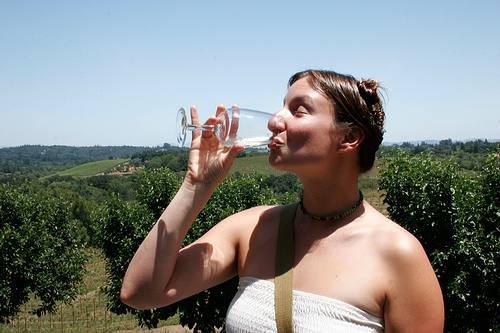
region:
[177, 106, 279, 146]
wine glass with a clear liquid in it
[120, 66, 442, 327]
a woman is drinking a clear liquid out of a wine glass on a very sunny day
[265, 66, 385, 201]
woman has brown hair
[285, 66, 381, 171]
hair is pinned up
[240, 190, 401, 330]
woman has a brown strap across her shoulder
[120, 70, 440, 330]
woman is using her right hand to drink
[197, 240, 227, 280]
you can see the reflection from the wine glass on the woman arm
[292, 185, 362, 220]
woman is wearing a necklace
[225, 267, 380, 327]
woman is wearing a tube top shirt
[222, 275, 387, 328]
tube top shirt is white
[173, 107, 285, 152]
an empty wine glass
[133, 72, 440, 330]
a woman drinking wine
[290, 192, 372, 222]
a beaded necklace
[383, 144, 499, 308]
a tree with dark green leaves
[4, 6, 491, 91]
a sunny blue sky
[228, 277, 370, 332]
a strapless white top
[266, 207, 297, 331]
a purse strap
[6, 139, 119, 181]
a mountain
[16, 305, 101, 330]
a metal fence by the trees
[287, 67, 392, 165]
dark hair pulled back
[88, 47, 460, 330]
woman holding wine glass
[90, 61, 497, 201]
woman with short hair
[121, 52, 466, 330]
woman wearing strapless top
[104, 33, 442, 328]
woman with brown hair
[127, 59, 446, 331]
woman with big nose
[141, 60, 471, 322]
woman wearing white top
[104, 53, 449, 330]
woman standing in vineyard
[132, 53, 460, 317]
woman with rosy cheeks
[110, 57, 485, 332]
woman with tan crossbody bag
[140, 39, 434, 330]
woman has clear glass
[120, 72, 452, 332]
a woman is drinking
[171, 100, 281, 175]
the woman holds a wine glass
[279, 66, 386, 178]
the woman's hair is up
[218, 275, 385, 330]
the woman wears a strapless white top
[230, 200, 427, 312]
the woman 's shoulders are bare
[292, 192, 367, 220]
the woman has a necklace on her neck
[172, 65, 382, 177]
the woman is drinking from a glass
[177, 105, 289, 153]
the wine glass is transparent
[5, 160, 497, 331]
there are bushes behind the woman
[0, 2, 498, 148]
the sky is blue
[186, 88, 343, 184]
the woman is drinking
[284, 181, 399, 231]
the woman is wearing necklace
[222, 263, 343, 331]
woman's top is white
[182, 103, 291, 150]
the glass is a wine glass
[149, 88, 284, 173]
the glass is transparent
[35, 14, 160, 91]
the sky is blue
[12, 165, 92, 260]
the bushes are green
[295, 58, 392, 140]
woman's hair is brown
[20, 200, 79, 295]
the trees are green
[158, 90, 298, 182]
the woman is drinking water